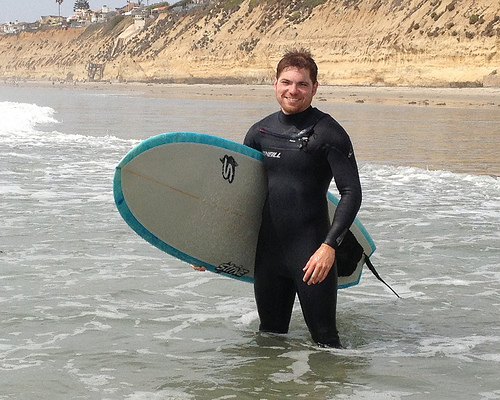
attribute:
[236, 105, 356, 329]
wet suit — black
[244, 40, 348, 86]
hair — brown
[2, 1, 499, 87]
hillside — sandy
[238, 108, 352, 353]
wetsuit — black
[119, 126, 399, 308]
surfboard — blue, white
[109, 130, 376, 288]
surfboard — blue, white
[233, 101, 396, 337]
suit — black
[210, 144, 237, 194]
insignia — Black , white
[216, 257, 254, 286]
letters — white, Black